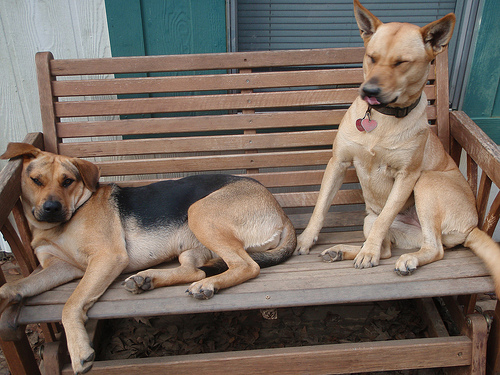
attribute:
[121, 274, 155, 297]
pads — paw , black, four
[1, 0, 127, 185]
wood — Gray 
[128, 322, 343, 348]
leaves — dead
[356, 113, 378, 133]
tags — heart shaped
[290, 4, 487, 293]
dog — lazy 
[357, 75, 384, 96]
nose — Black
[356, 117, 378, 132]
tag — heart shaped, pink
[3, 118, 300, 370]
dog — tan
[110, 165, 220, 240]
spot — black 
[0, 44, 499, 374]
wood bench — wood 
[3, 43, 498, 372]
bench — wooden, park, Brown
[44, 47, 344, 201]
bench — green 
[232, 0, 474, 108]
window — painted, Green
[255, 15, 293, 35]
blinds — window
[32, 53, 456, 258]
bench — wood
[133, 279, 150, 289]
feet — dog 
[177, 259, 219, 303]
pads — paw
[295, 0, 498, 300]
dog — blue, teal , sitting